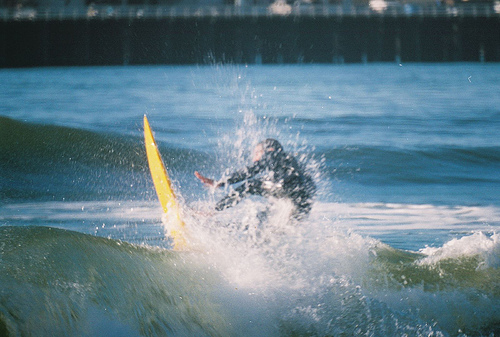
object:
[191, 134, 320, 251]
person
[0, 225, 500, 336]
wave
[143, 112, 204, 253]
surfboard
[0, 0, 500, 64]
bridge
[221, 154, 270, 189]
arm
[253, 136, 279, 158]
head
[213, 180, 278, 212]
leg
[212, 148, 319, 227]
wetsuit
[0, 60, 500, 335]
water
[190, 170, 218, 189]
hand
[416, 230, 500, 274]
wave cap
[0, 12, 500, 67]
wall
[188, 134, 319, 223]
armout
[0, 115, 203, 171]
waves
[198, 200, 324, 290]
foam